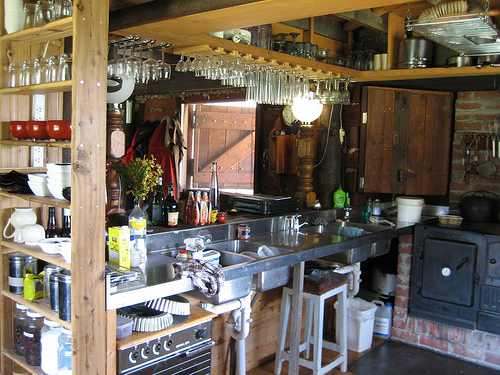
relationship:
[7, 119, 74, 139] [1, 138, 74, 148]
dishes on shelf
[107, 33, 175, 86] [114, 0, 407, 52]
glasses from ceiling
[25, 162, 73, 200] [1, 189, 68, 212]
dishes on shelf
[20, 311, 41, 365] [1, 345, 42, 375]
jar on shelf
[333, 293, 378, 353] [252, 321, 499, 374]
trashcan on floor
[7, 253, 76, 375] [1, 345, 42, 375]
canisters on shelf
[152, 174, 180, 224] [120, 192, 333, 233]
bottles on counter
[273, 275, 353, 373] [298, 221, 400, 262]
stool under sink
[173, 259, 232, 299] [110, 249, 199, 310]
towel on counter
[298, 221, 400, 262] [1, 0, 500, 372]
sink of kitchen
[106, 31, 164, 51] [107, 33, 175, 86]
rack for glasses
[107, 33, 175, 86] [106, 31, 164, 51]
glasses on rack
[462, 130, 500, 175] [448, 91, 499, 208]
utensils on wall